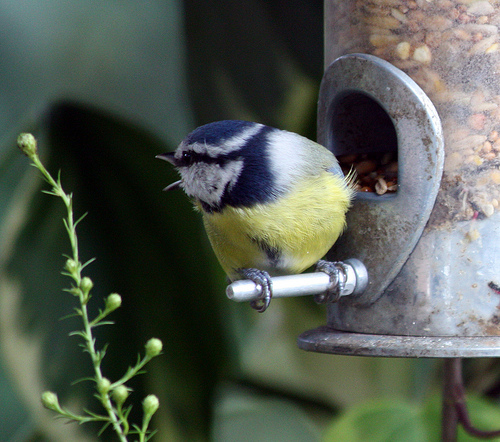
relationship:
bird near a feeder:
[149, 120, 361, 312] [295, 1, 499, 440]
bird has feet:
[149, 120, 361, 312] [239, 260, 349, 311]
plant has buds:
[14, 128, 165, 429] [10, 129, 159, 422]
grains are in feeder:
[321, 1, 498, 337] [295, 1, 499, 440]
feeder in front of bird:
[295, 1, 499, 440] [149, 120, 361, 312]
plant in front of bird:
[14, 128, 165, 429] [149, 120, 361, 312]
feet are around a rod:
[239, 260, 349, 311] [225, 254, 369, 306]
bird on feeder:
[149, 120, 361, 312] [295, 1, 499, 440]